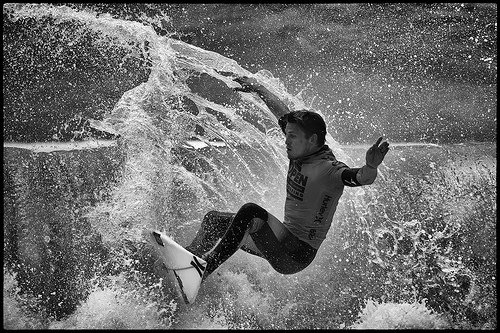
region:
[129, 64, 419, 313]
the man is surfing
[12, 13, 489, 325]
the picture is black and white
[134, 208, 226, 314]
the board is white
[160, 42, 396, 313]
the person is wet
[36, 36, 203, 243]
the waves are rough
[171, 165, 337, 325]
the pants are tight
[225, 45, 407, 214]
his hands are raised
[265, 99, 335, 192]
his hair is short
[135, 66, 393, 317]
the person is falling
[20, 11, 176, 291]
the water is falling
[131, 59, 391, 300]
a man riding a wave on the surfboard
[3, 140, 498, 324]
a large wave in the ocean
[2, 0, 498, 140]
the sky above the wave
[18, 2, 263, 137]
the splashing water above the wave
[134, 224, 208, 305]
the white surfboard the man is riding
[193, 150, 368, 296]
the wetsuit the man is wearing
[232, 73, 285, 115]
the man's arm touching the water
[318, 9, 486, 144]
drops of water above the wave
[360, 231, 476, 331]
more splashing water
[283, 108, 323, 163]
the man's head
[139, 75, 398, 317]
man on surfboard riding a wave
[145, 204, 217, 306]
surfboard cutting through a wave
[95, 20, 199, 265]
splash from surfboard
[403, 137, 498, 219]
wall of water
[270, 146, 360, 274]
white surf shirt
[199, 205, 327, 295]
dark colored surf pants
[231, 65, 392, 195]
man with arms outstretched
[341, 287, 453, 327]
white frothy splash from wave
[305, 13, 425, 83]
white spray from wave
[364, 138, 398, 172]
hand with fingers spread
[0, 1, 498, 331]
rough and wavy water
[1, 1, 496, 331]
black and white action photograph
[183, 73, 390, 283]
surfer wearing a wetsuit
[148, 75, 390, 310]
surfer on a surfboard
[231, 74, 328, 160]
right arm over head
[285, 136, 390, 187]
right arm out to side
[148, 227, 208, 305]
white surfboard in water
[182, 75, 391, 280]
surfer with dark hair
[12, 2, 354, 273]
wave crashing over surfer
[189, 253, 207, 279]
two stripes on surfboard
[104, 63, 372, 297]
a man is riding a surfboard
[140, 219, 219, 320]
a white surfboard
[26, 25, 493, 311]
black and white photo of a man on a surfboard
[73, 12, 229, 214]
the water splashes around the man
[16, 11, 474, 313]
man on board in what appears to be an indoor water park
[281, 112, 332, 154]
head of the man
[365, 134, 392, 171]
man's left hand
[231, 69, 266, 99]
man's right hand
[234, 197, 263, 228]
knee of the man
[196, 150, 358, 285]
man is wearing a wetsuit